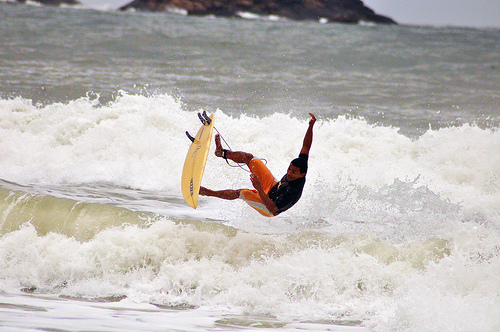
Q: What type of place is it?
A: It is an ocean.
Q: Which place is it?
A: It is an ocean.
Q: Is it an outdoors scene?
A: Yes, it is outdoors.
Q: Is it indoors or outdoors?
A: It is outdoors.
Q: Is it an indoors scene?
A: No, it is outdoors.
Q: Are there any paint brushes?
A: No, there are no paint brushes.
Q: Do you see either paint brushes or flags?
A: No, there are no paint brushes or flags.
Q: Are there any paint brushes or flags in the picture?
A: No, there are no paint brushes or flags.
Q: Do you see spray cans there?
A: No, there are no spray cans.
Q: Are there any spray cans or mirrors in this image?
A: No, there are no spray cans or mirrors.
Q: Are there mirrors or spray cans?
A: No, there are no spray cans or mirrors.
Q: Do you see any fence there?
A: No, there are no fences.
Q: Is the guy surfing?
A: Yes, the guy is surfing.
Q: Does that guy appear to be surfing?
A: Yes, the guy is surfing.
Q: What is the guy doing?
A: The guy is surfing.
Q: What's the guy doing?
A: The guy is surfing.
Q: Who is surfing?
A: The guy is surfing.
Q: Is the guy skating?
A: No, the guy is surfing.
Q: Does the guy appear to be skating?
A: No, the guy is surfing.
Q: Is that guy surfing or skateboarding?
A: The guy is surfing.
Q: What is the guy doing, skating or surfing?
A: The guy is surfing.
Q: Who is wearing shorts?
A: The guy is wearing shorts.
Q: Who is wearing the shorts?
A: The guy is wearing shorts.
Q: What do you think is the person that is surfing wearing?
A: The guy is wearing shorts.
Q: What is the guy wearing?
A: The guy is wearing shorts.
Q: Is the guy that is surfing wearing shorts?
A: Yes, the guy is wearing shorts.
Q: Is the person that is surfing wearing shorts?
A: Yes, the guy is wearing shorts.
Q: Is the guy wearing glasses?
A: No, the guy is wearing shorts.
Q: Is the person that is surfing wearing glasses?
A: No, the guy is wearing shorts.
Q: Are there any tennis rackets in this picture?
A: No, there are no tennis rackets.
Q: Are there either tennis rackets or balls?
A: No, there are no tennis rackets or balls.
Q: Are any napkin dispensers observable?
A: No, there are no napkin dispensers.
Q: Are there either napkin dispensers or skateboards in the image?
A: No, there are no napkin dispensers or skateboards.